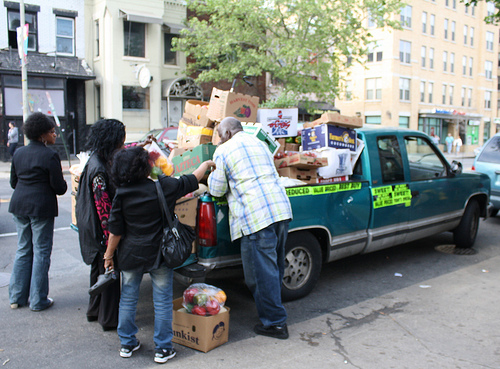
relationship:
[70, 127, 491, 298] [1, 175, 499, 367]
truck parked on street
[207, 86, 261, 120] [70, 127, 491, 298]
box piled on truck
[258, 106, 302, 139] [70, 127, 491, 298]
box piled on truck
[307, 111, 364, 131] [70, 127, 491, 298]
box piled on truck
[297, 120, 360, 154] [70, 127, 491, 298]
box piled on truck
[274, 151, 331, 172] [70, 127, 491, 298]
box piled on truck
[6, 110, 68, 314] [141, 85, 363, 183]
lady looking at boxes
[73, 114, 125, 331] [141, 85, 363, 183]
lady looking at boxes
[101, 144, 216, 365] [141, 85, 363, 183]
lady looking at boxes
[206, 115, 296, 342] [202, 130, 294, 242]
man wearing plaid jacket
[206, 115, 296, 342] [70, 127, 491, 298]
man leaning over truck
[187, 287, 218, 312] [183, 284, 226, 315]
produce in bag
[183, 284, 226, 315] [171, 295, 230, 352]
bag in box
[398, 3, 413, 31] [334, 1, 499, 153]
window on building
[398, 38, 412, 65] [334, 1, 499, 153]
window on building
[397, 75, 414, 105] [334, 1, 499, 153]
window on building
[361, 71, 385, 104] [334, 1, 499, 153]
window on building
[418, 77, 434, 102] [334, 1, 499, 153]
window on building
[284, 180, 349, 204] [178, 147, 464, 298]
black print on yellow strips across truck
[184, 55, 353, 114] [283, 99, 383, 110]
tree in front of building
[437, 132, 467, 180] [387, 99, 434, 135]
people standing in front of building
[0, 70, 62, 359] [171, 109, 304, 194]
lady checking items in truck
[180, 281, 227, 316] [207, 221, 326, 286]
bag of vegetables near truck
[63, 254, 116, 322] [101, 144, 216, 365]
sandles being held by lady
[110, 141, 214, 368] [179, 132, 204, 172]
lady getting mans attention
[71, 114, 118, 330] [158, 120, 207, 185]
lady shopping for vegetables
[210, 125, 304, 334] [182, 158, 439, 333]
man selling vegetables from h truck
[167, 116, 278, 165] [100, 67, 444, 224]
cargo loaded in bed of truck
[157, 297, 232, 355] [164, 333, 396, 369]
box of vegetables on street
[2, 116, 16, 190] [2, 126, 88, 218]
individual walking across street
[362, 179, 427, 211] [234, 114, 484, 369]
stickers on side of truck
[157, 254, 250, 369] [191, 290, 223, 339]
box containing colorful vegetables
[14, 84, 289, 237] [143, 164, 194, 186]
talking about cargo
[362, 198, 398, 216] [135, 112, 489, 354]
blue-green pickup truck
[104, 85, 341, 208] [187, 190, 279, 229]
empty boxes in back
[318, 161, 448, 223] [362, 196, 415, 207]
flourescent green advertisement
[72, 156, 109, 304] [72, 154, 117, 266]
sleeveless black sleeveless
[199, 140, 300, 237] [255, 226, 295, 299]
plaid jacket and blue jeans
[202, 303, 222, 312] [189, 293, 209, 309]
red yellow and green bell produce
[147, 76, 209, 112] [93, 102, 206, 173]
canopy over entrance